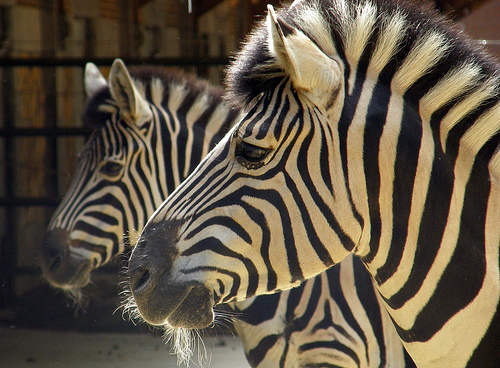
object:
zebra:
[129, 0, 499, 366]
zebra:
[40, 56, 416, 368]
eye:
[236, 142, 269, 161]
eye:
[102, 160, 122, 173]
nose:
[128, 220, 181, 320]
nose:
[40, 229, 72, 287]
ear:
[263, 1, 341, 109]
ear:
[80, 60, 106, 103]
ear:
[108, 57, 150, 125]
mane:
[223, 0, 499, 178]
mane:
[79, 63, 245, 132]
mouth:
[148, 277, 217, 332]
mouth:
[59, 258, 94, 293]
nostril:
[132, 262, 153, 292]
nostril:
[47, 254, 63, 273]